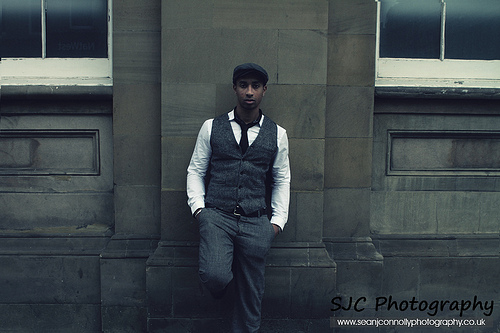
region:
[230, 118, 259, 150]
a worn black tie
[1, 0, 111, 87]
west closed window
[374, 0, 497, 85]
eastern window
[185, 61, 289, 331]
man standing up against a building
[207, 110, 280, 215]
a black and grey vest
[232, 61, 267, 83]
the man has on a fedora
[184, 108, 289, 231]
white button down shirt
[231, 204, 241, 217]
silver belt buckle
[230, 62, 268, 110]
the man is african american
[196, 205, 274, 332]
dark grey dress pants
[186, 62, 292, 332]
A man in a long sleeve white shirt and black cap leaning against a wall.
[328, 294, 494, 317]
SJC Photography in black.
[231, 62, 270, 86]
A black cap on a man.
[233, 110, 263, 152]
A black tie around a man's neck.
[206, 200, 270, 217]
A black belt with silver buckle.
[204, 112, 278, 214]
A dark grey button up vest.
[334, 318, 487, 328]
The web address www.seanjconnallyphotography.co.uk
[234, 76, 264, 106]
The black face of a man looking at the camera.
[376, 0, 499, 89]
White framed right side window.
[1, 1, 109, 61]
Two glass panels on a window to the left of a man.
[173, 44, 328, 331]
a guy standing by a wall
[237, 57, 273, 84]
the hat of a grown man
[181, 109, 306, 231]
the the shirt of a grown man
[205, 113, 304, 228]
the grey vest of a grown man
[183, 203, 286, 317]
the pants of a grown man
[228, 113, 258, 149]
the black tie of a grown man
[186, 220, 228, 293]
the right leg of a grown man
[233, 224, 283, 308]
the left leg of a grown man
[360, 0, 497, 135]
a large white window on a building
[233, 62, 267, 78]
this is a gray hat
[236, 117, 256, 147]
this is a black tie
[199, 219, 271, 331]
these are gray pants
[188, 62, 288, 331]
this is a man with his hands in his pocket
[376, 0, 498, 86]
this is a shut window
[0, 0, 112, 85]
this window is shut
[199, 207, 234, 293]
this leg is up against the wall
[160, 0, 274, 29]
this stone brick is a part of the building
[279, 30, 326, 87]
this is a stone brick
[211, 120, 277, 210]
this is a gray vest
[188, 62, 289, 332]
a man is standing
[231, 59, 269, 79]
hat on a man's head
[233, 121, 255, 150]
a man's black tie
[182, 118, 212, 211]
white sleeve of a shirt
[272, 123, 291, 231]
white sleeve of a shirt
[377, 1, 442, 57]
a pane of a window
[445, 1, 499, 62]
a pane of a window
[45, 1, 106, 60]
a pane of a window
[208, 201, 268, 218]
a belt on a man's waist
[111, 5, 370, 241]
a setion of brick wall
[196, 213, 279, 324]
man is wearing pants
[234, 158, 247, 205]
buttons on the vest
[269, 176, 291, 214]
long sleeve shirt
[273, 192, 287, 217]
sleeves are white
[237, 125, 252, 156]
man is wearing a tie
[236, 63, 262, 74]
a hat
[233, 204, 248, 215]
a belt